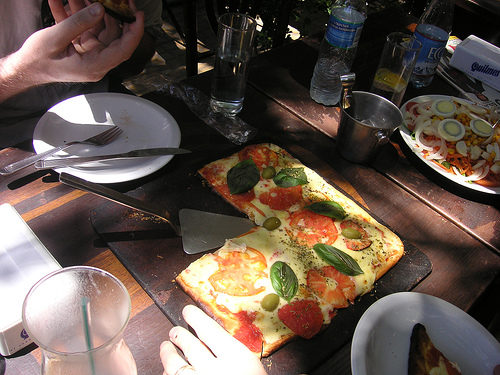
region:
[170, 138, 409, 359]
a square pizza with one slice missing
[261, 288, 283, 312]
a green olive on the top of the pizza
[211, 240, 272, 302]
a tomato slice on the top of the pizza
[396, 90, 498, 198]
a salad with eggs in it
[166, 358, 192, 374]
a ring on the person's finger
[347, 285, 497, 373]
a plate with a piece of pizza in it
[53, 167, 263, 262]
a spatula for serving pizza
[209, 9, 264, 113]
a half full glass on the table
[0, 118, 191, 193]
a fork and knife on the plate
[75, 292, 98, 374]
a straw in the glass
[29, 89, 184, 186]
A white plate is sitting on a table.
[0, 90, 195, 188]
A knife and fork are sitting in a plate.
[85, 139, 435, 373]
A platter is sitting on a table.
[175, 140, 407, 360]
A pizza is sitting on a platter.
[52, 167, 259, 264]
A utensil is sitting next to a pizza.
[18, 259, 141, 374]
A glass is sitting on a table.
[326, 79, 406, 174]
A metal cup is sitting on a table.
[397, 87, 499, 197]
A plate has food in it.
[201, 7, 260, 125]
A glass filled with liquid is sitting on a table.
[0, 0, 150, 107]
A person is holding a piece of food in their hands.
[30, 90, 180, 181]
an empty white plate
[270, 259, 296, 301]
a basil leaf on a pizza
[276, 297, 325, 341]
a tomato slice on a pizza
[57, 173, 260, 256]
a pie server under a pizza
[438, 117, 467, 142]
a hard boiled egg on a salad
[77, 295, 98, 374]
a straw in a cup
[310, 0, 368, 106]
a water bottle on a table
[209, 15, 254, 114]
a glass of water on a table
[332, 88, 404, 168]
a metal bucket on a table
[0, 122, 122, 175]
a fork on a plate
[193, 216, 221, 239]
the spatula is silver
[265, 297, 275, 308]
the olive is olive color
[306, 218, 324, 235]
the tomato is red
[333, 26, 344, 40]
the label is blue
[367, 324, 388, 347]
the plate is white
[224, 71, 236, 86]
the liquid is clear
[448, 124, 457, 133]
the yoke is yellow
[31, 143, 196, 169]
a knife on a plate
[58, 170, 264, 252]
a spatula on a table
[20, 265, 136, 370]
a glass on a table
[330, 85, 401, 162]
a metal cup on a table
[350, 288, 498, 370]
a plate on a table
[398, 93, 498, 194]
a plate on a table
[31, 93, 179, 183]
a plate on a table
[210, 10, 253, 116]
a glass on a table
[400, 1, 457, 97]
a bottle on a table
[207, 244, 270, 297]
slice of tomato on pizza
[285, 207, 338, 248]
slice of tomato on pizza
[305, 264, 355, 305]
slice of tomato on pizza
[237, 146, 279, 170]
slice of tomato on pizza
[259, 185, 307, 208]
slice of tomato on pizza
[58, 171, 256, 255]
spatula beneath flat pizza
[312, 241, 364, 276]
topping on flat pizza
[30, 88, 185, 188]
small white plate with eating utensils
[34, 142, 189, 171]
butter knife on top of white plate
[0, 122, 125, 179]
fork on top of white plate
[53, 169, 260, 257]
large spatula for serving pizza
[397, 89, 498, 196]
large salad with boiled eggs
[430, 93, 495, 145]
three slices of boiled egg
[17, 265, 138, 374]
hurricane glass with straw